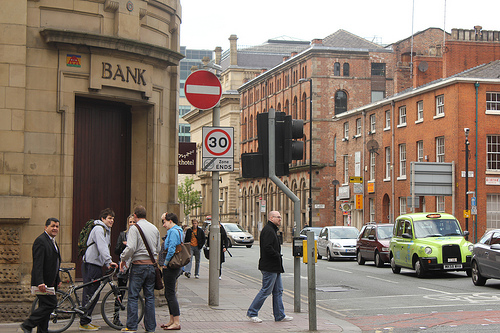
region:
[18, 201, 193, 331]
People standing on street corner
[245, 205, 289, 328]
Man waiting to cross street.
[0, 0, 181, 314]
Bank on the corner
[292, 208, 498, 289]
Cars parked along curb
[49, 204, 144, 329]
Man in grey hoodie holding bike.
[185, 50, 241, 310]
Street signs attached to post.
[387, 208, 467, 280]
Yellow car is second in line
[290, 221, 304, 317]
Parking meter along curb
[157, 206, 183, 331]
Woman wearing blue sweater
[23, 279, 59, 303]
Newspaper in man's right hand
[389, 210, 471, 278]
Lime green taxi cab on road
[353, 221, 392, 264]
Red hatchback on the road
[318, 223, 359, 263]
silver sedan on the road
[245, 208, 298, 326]
Man with black jacket waiting to cross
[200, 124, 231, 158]
White sign with red circle and number 30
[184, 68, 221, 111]
Red and white do not enter sign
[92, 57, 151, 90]
Bank sign on side of building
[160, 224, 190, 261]
blue jacket worn by lady on sidewalk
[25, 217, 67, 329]
Man in a business suit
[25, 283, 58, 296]
newspaper held by a pedestrian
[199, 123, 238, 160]
A speed limit sign on the corner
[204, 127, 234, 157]
A red circle encompassing the number 30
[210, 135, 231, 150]
Black writing on the white sign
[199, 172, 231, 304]
A thick metal sign pole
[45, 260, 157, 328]
A black bike on the sidewalk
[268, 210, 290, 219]
The man is balding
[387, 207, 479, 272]
An oddly shaped green vehicle on the road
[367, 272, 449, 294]
Dashed white lines on the road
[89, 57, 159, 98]
The word "Bank" above the building's entrance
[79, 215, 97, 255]
A green backpack on the young man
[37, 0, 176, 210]
a bank building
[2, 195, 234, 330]
people on the sidewalk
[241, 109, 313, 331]
street light next to the road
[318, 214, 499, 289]
cars in the street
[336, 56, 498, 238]
a red building with lots of windows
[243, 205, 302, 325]
a man in a black jacket and blue pants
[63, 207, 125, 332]
a man with a bicycle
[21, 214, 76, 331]
man in a black suite with a news paper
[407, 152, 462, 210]
an empty store sign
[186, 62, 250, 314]
street signs on a pole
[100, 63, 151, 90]
sign for a bank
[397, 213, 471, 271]
green car with a black fender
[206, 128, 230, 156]
sign with a number 30 in a red circle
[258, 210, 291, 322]
man wearing jeans and a black coat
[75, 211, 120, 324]
man with a backpack and a bicycle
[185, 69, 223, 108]
round red sign with a white bar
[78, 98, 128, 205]
brown door under the bank sign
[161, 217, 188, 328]
woman wearing a blue jacket and ankle length jeans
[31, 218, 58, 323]
man in a black suit jacket carrying a newspaper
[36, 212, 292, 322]
group of people on the sidewalk